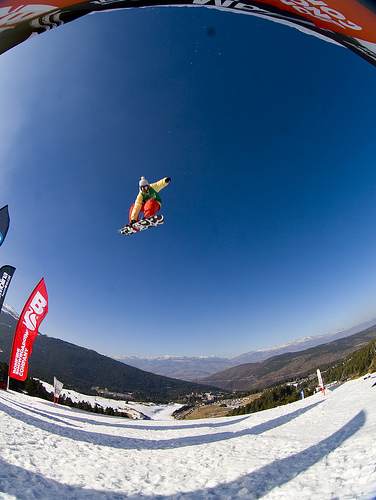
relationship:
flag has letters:
[10, 266, 59, 388] [22, 283, 50, 338]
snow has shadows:
[3, 382, 373, 495] [8, 393, 310, 453]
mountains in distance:
[12, 319, 372, 404] [1, 103, 374, 422]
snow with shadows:
[3, 382, 373, 495] [8, 393, 310, 453]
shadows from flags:
[8, 393, 310, 453] [2, 4, 375, 66]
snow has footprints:
[3, 382, 373, 495] [205, 448, 303, 497]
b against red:
[28, 287, 52, 315] [10, 266, 59, 388]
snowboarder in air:
[112, 161, 195, 249] [8, 49, 371, 351]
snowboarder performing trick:
[112, 161, 195, 249] [103, 156, 195, 420]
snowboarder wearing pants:
[112, 161, 195, 249] [127, 198, 167, 224]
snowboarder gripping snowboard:
[112, 161, 195, 249] [120, 213, 164, 234]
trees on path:
[19, 374, 140, 422] [3, 363, 223, 498]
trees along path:
[19, 374, 140, 422] [3, 363, 223, 498]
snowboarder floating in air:
[112, 161, 195, 249] [8, 49, 371, 351]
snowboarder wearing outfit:
[112, 161, 195, 249] [129, 179, 173, 217]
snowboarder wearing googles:
[112, 161, 195, 249] [138, 183, 153, 191]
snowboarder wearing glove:
[112, 161, 195, 249] [161, 172, 173, 186]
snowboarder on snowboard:
[112, 161, 195, 249] [120, 213, 164, 234]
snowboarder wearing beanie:
[112, 161, 195, 249] [136, 174, 152, 188]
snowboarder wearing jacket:
[112, 161, 195, 249] [129, 177, 188, 213]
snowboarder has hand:
[112, 161, 195, 249] [126, 216, 143, 228]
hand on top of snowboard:
[126, 216, 143, 228] [120, 213, 164, 234]